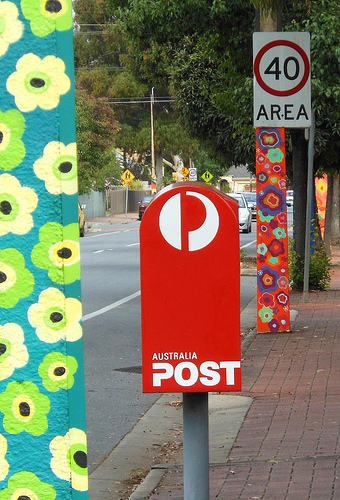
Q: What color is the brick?
A: Red.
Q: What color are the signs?
A: Red, white, and black.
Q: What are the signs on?
A: Posts.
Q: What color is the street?
A: Gray.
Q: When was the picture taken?
A: Daytime.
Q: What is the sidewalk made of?
A: Brick.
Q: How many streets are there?
A: One.